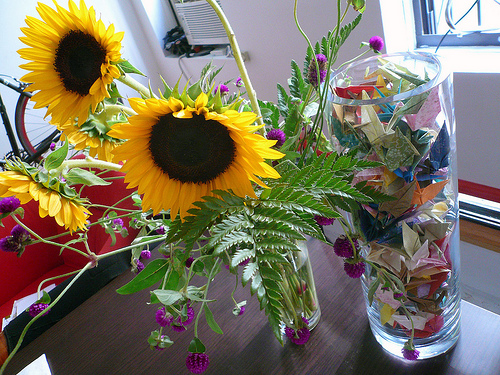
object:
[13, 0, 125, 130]
sunflower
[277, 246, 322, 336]
vase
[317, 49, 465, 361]
vase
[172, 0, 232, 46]
air conditioner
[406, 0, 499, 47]
window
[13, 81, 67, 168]
wheel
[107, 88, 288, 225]
sunflowers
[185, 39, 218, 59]
cord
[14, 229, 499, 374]
table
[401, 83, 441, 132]
origami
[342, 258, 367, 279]
flowers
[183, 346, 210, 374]
flowers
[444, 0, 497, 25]
light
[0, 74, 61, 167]
spokes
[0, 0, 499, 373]
image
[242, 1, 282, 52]
wall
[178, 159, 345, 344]
leaves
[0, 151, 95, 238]
couch